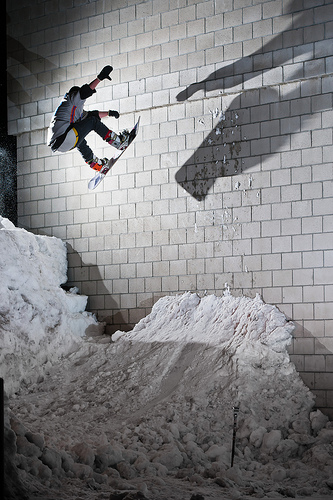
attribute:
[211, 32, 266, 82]
brick — white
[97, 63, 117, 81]
glove — black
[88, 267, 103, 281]
brick — white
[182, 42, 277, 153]
wall — brick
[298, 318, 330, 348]
brick — white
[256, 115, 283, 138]
brick — white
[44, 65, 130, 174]
person — wearing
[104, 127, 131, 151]
boot — snow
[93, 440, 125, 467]
clump — round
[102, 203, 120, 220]
brick — white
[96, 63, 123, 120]
gloves — black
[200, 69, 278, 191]
brick — White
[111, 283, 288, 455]
ramp — snow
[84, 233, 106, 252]
brick — white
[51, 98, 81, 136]
shirt — gray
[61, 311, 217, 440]
snow — huge mound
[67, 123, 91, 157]
belt — yellow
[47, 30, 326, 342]
wall — brick, white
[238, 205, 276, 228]
brick — White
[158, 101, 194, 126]
brick — White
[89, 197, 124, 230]
brick — White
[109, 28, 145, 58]
brick — White